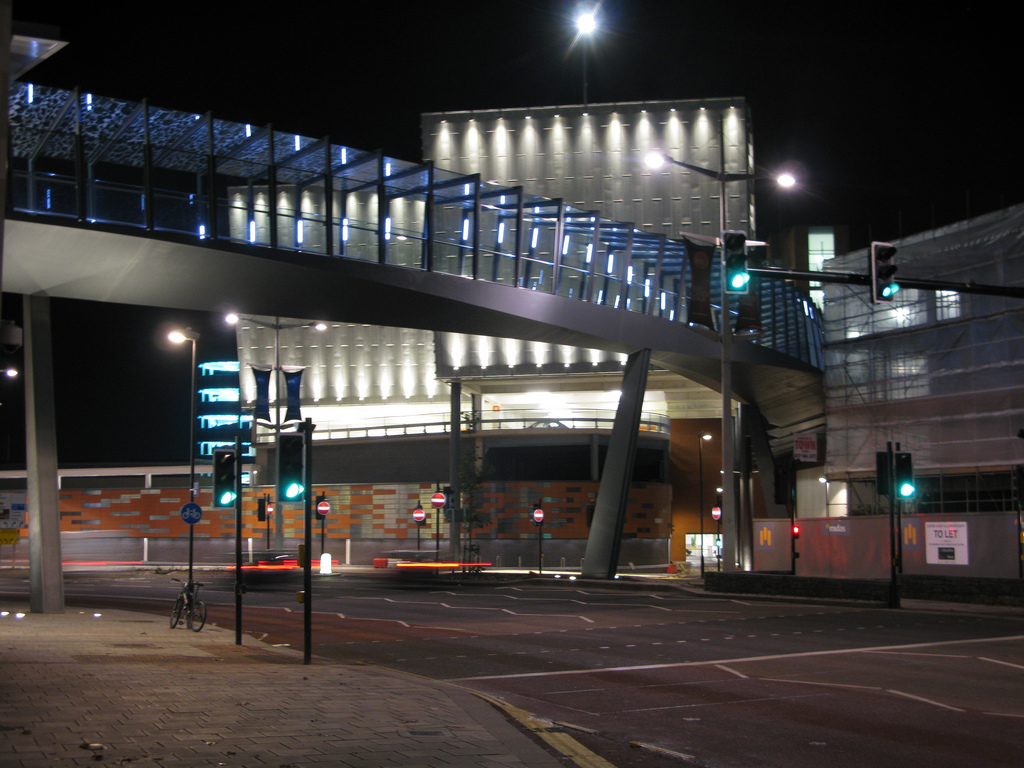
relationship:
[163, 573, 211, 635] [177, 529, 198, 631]
bicycle leaning on pole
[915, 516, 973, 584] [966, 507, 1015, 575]
poster on fence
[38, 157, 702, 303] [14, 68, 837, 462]
glass around walkway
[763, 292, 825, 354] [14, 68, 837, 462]
glass around walkway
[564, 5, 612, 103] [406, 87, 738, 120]
light on roof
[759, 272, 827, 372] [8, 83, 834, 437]
glass covered walkway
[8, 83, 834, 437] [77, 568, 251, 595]
walkway over road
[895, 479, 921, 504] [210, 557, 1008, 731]
light over road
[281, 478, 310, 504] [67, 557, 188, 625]
light over road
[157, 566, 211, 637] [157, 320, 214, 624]
bicycle chained to streetlamp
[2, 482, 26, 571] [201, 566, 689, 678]
wall pattern along road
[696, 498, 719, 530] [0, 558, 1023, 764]
signs along city lane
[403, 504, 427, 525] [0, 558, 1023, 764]
signs along city lane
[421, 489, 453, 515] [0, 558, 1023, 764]
signs along city lane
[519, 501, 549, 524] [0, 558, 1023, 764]
signs along city lane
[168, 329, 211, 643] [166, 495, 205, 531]
streetlamp with sign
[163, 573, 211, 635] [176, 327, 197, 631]
bicycle chained to a pole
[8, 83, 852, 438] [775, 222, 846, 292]
walkway from building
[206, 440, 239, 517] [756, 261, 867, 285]
light on pole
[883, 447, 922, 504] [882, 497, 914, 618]
light on pole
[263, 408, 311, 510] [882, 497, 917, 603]
light on pole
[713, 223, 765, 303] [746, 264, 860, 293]
light on pole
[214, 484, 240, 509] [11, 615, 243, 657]
light at sidewalk